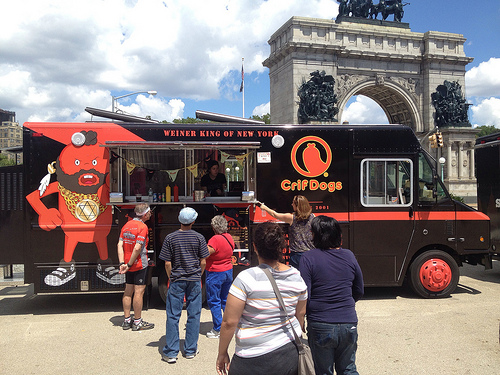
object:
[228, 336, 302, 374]
gray pants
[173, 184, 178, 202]
ketchup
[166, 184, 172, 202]
bottles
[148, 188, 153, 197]
bottles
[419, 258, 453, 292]
hub caps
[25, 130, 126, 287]
caricature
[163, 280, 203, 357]
blue jeans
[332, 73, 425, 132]
archway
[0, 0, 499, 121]
sky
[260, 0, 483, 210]
structure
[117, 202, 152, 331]
man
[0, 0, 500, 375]
scene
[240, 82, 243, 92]
flag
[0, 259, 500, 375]
ground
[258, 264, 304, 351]
strap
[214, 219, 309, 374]
woman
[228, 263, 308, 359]
shirt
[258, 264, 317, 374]
bag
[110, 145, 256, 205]
window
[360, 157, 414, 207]
window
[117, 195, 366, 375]
people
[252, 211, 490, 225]
line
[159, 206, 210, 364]
man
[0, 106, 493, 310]
food truck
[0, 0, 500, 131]
clouds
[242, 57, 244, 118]
pole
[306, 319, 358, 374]
jeans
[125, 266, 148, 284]
shorts